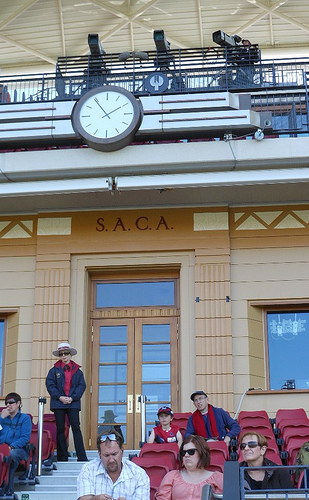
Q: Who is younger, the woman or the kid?
A: The kid is younger than the woman.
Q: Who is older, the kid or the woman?
A: The woman is older than the kid.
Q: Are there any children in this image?
A: Yes, there is a child.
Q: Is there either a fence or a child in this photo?
A: Yes, there is a child.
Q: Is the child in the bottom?
A: Yes, the child is in the bottom of the image.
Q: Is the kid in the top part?
A: No, the kid is in the bottom of the image.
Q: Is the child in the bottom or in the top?
A: The child is in the bottom of the image.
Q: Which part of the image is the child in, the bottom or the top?
A: The child is in the bottom of the image.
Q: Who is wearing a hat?
A: The child is wearing a hat.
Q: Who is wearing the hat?
A: The child is wearing a hat.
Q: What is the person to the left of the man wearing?
A: The child is wearing a hat.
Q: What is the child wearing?
A: The child is wearing a hat.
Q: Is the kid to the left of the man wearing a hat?
A: Yes, the kid is wearing a hat.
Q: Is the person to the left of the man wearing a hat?
A: Yes, the kid is wearing a hat.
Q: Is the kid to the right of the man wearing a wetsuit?
A: No, the kid is wearing a hat.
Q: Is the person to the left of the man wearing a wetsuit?
A: No, the kid is wearing a hat.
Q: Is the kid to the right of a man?
A: Yes, the kid is to the right of a man.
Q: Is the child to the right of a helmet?
A: No, the child is to the right of a man.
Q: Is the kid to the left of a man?
A: No, the kid is to the right of a man.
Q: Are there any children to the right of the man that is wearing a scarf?
A: Yes, there is a child to the right of the man.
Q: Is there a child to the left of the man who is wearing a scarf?
A: No, the child is to the right of the man.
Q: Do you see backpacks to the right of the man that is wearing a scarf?
A: No, there is a child to the right of the man.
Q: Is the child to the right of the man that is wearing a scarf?
A: Yes, the child is to the right of the man.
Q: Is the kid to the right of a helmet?
A: No, the kid is to the right of the man.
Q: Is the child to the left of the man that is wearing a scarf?
A: No, the child is to the right of the man.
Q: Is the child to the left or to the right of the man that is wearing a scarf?
A: The child is to the right of the man.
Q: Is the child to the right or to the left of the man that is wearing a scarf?
A: The child is to the right of the man.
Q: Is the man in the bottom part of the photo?
A: Yes, the man is in the bottom of the image.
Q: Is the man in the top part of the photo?
A: No, the man is in the bottom of the image.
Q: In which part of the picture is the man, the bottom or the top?
A: The man is in the bottom of the image.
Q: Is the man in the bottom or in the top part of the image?
A: The man is in the bottom of the image.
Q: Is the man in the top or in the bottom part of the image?
A: The man is in the bottom of the image.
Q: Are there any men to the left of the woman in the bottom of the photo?
A: Yes, there is a man to the left of the woman.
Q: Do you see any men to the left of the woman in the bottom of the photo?
A: Yes, there is a man to the left of the woman.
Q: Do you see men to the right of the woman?
A: No, the man is to the left of the woman.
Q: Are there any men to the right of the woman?
A: No, the man is to the left of the woman.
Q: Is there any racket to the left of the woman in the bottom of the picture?
A: No, there is a man to the left of the woman.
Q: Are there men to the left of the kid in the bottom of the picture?
A: Yes, there is a man to the left of the kid.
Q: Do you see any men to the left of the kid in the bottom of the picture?
A: Yes, there is a man to the left of the kid.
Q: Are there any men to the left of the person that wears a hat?
A: Yes, there is a man to the left of the kid.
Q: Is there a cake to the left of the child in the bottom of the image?
A: No, there is a man to the left of the kid.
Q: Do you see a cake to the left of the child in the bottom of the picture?
A: No, there is a man to the left of the kid.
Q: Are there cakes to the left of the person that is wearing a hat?
A: No, there is a man to the left of the kid.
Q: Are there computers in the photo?
A: No, there are no computers.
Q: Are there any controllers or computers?
A: No, there are no computers or controllers.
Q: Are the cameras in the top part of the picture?
A: Yes, the cameras are in the top of the image.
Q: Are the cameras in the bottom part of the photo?
A: No, the cameras are in the top of the image.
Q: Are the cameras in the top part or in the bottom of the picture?
A: The cameras are in the top of the image.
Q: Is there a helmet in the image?
A: No, there are no helmets.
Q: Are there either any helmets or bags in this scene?
A: No, there are no helmets or bags.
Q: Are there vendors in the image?
A: No, there are no vendors.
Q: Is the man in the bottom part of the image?
A: Yes, the man is in the bottom of the image.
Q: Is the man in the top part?
A: No, the man is in the bottom of the image.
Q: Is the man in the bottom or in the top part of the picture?
A: The man is in the bottom of the image.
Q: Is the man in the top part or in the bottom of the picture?
A: The man is in the bottom of the image.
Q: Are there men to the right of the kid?
A: Yes, there is a man to the right of the kid.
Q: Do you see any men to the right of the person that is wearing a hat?
A: Yes, there is a man to the right of the kid.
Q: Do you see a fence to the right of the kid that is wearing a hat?
A: No, there is a man to the right of the child.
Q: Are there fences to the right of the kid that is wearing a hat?
A: No, there is a man to the right of the child.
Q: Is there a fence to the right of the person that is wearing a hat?
A: No, there is a man to the right of the child.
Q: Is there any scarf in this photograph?
A: Yes, there is a scarf.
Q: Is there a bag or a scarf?
A: Yes, there is a scarf.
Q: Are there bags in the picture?
A: No, there are no bags.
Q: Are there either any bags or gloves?
A: No, there are no bags or gloves.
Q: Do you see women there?
A: Yes, there is a woman.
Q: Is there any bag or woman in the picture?
A: Yes, there is a woman.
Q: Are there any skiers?
A: No, there are no skiers.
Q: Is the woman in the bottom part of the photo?
A: Yes, the woman is in the bottom of the image.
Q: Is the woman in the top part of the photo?
A: No, the woman is in the bottom of the image.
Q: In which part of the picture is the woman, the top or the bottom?
A: The woman is in the bottom of the image.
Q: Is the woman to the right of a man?
A: Yes, the woman is to the right of a man.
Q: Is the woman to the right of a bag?
A: No, the woman is to the right of a man.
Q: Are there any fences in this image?
A: No, there are no fences.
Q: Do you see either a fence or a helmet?
A: No, there are no fences or helmets.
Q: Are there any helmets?
A: No, there are no helmets.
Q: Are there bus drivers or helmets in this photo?
A: No, there are no helmets or bus drivers.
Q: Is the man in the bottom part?
A: Yes, the man is in the bottom of the image.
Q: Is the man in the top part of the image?
A: No, the man is in the bottom of the image.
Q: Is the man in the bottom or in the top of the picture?
A: The man is in the bottom of the image.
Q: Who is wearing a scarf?
A: The man is wearing a scarf.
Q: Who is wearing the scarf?
A: The man is wearing a scarf.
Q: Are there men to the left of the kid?
A: Yes, there is a man to the left of the kid.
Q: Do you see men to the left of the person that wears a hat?
A: Yes, there is a man to the left of the kid.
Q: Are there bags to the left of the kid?
A: No, there is a man to the left of the kid.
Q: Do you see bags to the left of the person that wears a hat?
A: No, there is a man to the left of the kid.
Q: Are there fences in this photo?
A: No, there are no fences.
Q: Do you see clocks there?
A: Yes, there is a clock.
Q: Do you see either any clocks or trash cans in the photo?
A: Yes, there is a clock.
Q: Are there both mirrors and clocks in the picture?
A: No, there is a clock but no mirrors.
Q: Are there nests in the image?
A: No, there are no nests.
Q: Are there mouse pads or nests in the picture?
A: No, there are no nests or mouse pads.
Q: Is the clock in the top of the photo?
A: Yes, the clock is in the top of the image.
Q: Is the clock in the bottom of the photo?
A: No, the clock is in the top of the image.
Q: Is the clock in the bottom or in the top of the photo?
A: The clock is in the top of the image.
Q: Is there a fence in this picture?
A: No, there are no fences.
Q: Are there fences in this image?
A: No, there are no fences.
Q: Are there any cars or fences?
A: No, there are no fences or cars.